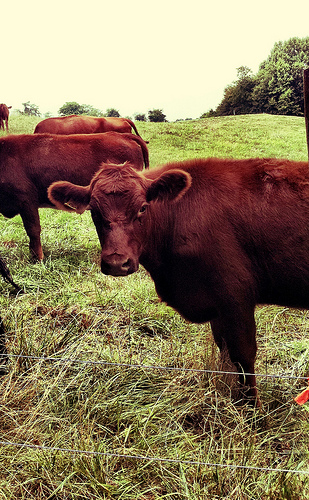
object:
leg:
[19, 205, 43, 262]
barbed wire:
[0, 352, 309, 380]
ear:
[144, 168, 192, 205]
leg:
[218, 311, 259, 418]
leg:
[209, 314, 233, 369]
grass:
[0, 110, 306, 500]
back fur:
[170, 156, 309, 174]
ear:
[46, 178, 91, 216]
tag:
[64, 199, 77, 211]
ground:
[0, 112, 309, 500]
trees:
[223, 60, 256, 119]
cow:
[34, 113, 150, 144]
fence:
[0, 335, 307, 480]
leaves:
[279, 96, 282, 99]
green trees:
[253, 36, 309, 116]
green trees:
[57, 102, 106, 119]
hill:
[0, 112, 306, 500]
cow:
[0, 103, 11, 132]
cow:
[47, 158, 309, 410]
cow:
[0, 132, 150, 265]